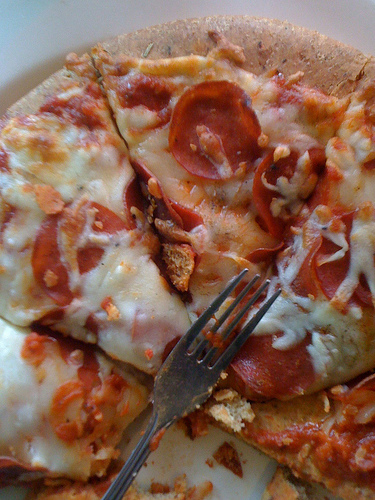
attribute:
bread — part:
[3, 5, 374, 151]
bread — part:
[119, 15, 344, 58]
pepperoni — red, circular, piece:
[170, 80, 266, 179]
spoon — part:
[138, 265, 290, 360]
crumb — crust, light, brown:
[33, 182, 65, 216]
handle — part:
[82, 414, 179, 498]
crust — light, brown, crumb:
[80, 0, 363, 94]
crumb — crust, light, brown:
[92, 215, 104, 231]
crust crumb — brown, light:
[1, 16, 373, 497]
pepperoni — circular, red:
[167, 77, 283, 184]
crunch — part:
[206, 459, 266, 474]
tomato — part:
[201, 106, 219, 144]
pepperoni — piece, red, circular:
[168, 75, 268, 188]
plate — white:
[154, 444, 201, 472]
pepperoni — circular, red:
[162, 78, 273, 186]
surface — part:
[173, 428, 279, 495]